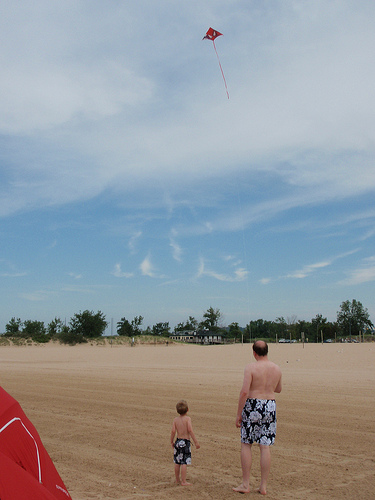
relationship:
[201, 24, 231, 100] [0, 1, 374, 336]
kite in sky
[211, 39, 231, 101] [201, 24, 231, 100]
string part of kite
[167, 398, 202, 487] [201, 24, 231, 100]
boy watching kite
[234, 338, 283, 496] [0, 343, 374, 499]
man standing on sand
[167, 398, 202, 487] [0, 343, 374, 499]
boy standing on sand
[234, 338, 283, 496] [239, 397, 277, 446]
man wearing shorts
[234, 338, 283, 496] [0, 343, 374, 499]
man standing on beach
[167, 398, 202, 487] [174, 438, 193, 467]
boy wearing shorts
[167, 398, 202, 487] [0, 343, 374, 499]
boy standing on beach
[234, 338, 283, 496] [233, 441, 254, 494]
man has leg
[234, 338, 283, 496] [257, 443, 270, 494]
man has leg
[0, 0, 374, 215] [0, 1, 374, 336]
cloud in sky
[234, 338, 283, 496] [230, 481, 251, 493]
man has foot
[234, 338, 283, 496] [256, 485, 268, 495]
man has foot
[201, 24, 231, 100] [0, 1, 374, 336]
kite flying in sky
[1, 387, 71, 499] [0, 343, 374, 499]
tent sitting on sand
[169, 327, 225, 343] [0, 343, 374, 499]
beach house standing on sand